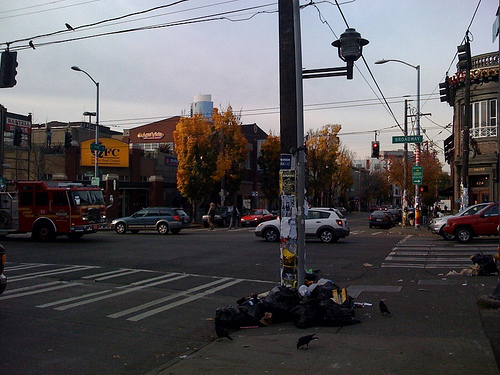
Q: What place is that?
A: Intersection.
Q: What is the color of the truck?
A: Red.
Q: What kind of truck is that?
A: Firetruck.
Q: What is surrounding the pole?
A: Garbage.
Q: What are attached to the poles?
A: Power lines.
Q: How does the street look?
A: Dirty.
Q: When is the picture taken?
A: Daytime.